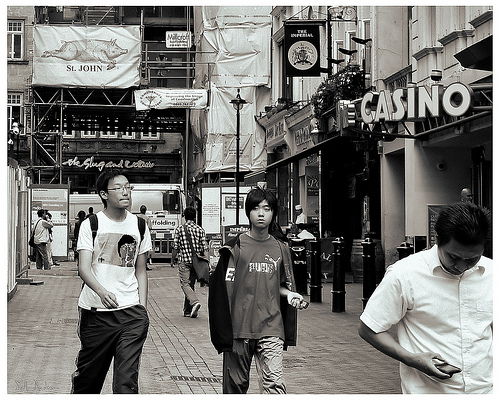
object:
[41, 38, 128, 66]
pig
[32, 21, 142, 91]
sign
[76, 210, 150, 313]
shirt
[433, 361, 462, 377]
cell phone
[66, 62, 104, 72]
st john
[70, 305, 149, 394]
pants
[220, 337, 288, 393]
pants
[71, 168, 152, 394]
guy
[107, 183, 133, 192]
glasses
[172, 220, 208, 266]
shirt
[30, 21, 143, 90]
banner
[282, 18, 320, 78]
banner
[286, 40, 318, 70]
seal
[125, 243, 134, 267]
beatles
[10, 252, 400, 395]
street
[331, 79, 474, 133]
sign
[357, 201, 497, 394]
guy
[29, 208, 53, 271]
person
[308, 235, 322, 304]
post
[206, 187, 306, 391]
kid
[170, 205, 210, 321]
man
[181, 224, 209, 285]
backpack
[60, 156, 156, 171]
sign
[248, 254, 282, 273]
logo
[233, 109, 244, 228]
lamppost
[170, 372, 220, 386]
grate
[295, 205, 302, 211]
hat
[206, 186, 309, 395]
man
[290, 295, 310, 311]
cell phone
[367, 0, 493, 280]
building